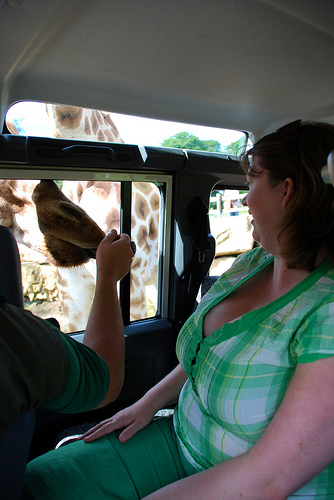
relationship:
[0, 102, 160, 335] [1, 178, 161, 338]
giraffe outside window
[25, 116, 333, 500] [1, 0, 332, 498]
woman in bus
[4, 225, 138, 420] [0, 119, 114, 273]
arm feeding giraffe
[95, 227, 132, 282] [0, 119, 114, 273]
hand feeding giraffe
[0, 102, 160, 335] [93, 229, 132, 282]
giraffe eating from hand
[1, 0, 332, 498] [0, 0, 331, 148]
bus has top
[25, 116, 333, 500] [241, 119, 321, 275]
woman with hair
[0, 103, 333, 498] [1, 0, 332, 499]
passengers in vehicle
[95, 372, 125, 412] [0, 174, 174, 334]
elbow below window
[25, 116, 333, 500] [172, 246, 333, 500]
woman wearing shirt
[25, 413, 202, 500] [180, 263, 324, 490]
green pants match top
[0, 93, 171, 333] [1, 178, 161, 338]
giraffe through window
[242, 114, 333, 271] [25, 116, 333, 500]
brown hair on woman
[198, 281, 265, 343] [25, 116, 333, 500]
cleveage on woman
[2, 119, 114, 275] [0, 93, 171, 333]
head on giraffe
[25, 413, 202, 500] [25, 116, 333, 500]
green pants on woman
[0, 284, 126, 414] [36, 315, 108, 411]
arm in sleeve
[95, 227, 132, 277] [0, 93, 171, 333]
hand touching giraffe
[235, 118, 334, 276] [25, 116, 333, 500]
brown hair on woman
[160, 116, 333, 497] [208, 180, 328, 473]
woman watching from distance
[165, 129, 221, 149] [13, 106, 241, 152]
tops in sunlight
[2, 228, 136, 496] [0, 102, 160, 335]
someone feeding giraffe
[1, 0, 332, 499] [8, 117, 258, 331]
vehicle at park